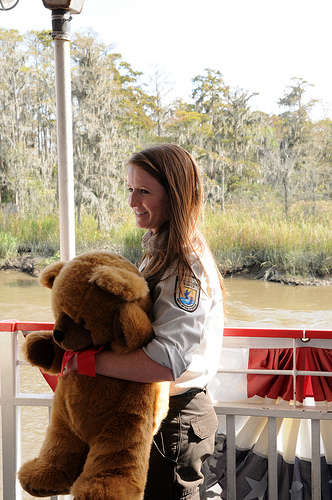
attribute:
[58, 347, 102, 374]
ribbon — red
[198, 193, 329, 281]
grass — tall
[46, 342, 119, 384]
ribbon — red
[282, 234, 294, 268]
grass — green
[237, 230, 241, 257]
grass — green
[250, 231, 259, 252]
grass — green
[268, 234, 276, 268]
grass — green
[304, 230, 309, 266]
grass — green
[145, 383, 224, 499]
pants — black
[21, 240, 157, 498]
bear — stuffed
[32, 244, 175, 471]
bear — brown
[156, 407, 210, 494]
pants — black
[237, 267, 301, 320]
river — dirty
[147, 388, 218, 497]
shorts — black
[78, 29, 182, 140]
trees — tall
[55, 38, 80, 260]
lampstand — white, long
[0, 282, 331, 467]
water — brown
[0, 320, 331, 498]
railing — metal, white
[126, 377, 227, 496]
trouser — black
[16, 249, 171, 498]
teddy bear — brown, large